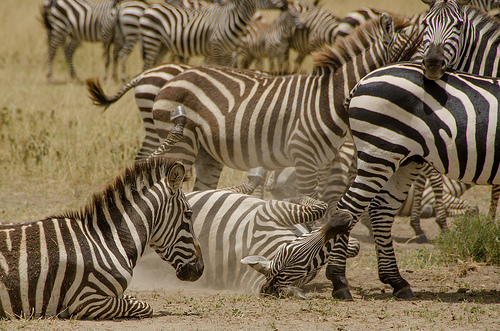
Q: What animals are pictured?
A: Zebras.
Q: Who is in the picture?
A: No one.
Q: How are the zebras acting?
A: Relaxed.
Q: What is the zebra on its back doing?
A: Scratching.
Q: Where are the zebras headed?
A: Right.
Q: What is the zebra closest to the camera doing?
A: Laying down.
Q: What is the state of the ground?
A: Dry.